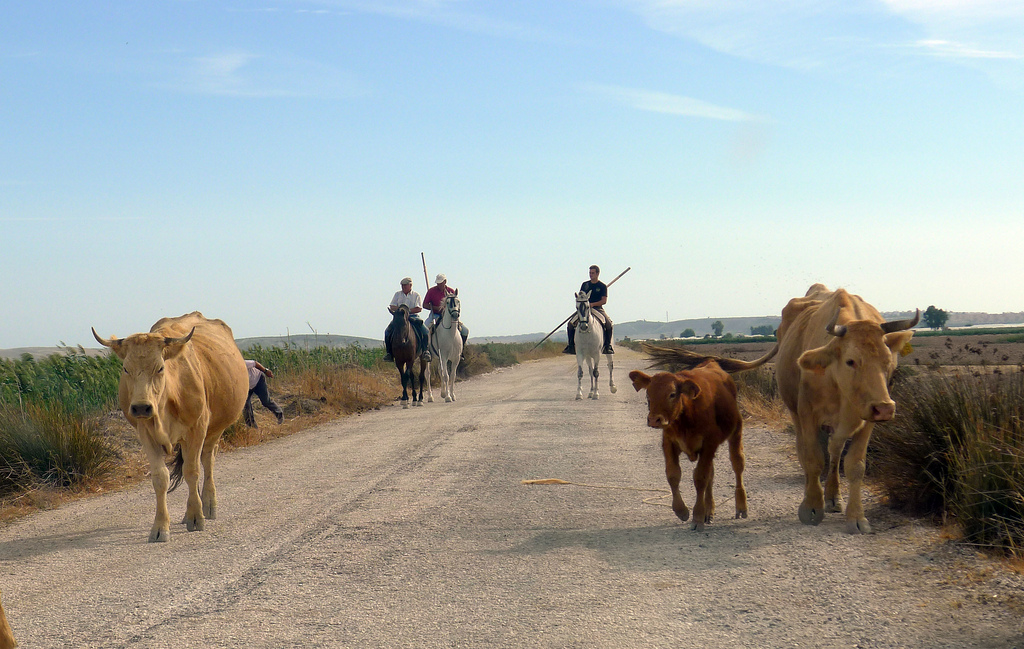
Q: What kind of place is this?
A: It is a road.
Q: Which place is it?
A: It is a road.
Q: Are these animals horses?
A: No, there are both horses and cows.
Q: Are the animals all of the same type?
A: No, there are both horses and cows.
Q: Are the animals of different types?
A: Yes, they are horses and cows.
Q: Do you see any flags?
A: No, there are no flags.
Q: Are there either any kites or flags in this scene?
A: No, there are no flags or kites.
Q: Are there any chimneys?
A: No, there are no chimneys.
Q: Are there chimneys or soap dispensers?
A: No, there are no chimneys or soap dispensers.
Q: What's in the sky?
A: The clouds are in the sky.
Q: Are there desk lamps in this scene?
A: No, there are no desk lamps.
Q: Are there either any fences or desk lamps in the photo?
A: No, there are no desk lamps or fences.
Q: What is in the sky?
A: The clouds are in the sky.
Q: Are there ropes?
A: No, there are no ropes.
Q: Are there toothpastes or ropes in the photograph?
A: No, there are no ropes or toothpastes.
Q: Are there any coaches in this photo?
A: No, there are no coaches.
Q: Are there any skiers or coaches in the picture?
A: No, there are no coaches or skiers.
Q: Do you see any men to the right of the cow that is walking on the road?
A: Yes, there is a man to the right of the cow.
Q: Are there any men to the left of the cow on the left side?
A: No, the man is to the right of the cow.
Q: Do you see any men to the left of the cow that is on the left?
A: No, the man is to the right of the cow.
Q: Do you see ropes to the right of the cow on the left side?
A: No, there is a man to the right of the cow.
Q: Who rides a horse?
A: The man rides a horse.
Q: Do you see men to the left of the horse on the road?
A: Yes, there is a man to the left of the horse.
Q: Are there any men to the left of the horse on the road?
A: Yes, there is a man to the left of the horse.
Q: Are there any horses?
A: Yes, there is a horse.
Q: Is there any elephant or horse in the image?
A: Yes, there is a horse.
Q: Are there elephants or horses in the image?
A: Yes, there is a horse.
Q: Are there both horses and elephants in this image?
A: No, there is a horse but no elephants.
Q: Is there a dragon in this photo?
A: No, there are no dragons.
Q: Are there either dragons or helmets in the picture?
A: No, there are no dragons or helmets.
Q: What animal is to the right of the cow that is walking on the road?
A: The animal is a horse.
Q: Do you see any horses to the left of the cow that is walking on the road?
A: No, the horse is to the right of the cow.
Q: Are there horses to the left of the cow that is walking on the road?
A: No, the horse is to the right of the cow.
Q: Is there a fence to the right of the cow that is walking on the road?
A: No, there is a horse to the right of the cow.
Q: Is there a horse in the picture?
A: Yes, there is a horse.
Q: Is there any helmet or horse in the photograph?
A: Yes, there is a horse.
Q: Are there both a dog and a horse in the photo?
A: No, there is a horse but no dogs.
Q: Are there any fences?
A: No, there are no fences.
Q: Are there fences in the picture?
A: No, there are no fences.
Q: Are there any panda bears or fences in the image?
A: No, there are no fences or panda bears.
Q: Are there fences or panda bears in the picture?
A: No, there are no fences or panda bears.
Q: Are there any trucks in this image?
A: No, there are no trucks.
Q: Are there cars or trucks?
A: No, there are no trucks or cars.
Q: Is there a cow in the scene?
A: Yes, there is a cow.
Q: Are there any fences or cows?
A: Yes, there is a cow.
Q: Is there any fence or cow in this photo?
A: Yes, there is a cow.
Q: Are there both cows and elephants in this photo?
A: No, there is a cow but no elephants.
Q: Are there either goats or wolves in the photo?
A: No, there are no goats or wolves.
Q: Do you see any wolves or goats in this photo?
A: No, there are no goats or wolves.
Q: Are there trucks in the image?
A: No, there are no trucks.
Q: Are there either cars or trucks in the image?
A: No, there are no trucks or cars.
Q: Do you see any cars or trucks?
A: No, there are no trucks or cars.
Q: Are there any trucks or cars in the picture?
A: No, there are no trucks or cars.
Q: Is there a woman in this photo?
A: No, there are no women.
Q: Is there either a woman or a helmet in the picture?
A: No, there are no women or helmets.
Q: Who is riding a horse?
A: The man is riding a horse.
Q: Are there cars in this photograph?
A: No, there are no cars.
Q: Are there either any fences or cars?
A: No, there are no cars or fences.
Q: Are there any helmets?
A: No, there are no helmets.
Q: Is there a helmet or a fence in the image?
A: No, there are no helmets or fences.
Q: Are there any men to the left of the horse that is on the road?
A: Yes, there is a man to the left of the horse.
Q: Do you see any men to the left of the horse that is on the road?
A: Yes, there is a man to the left of the horse.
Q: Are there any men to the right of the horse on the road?
A: No, the man is to the left of the horse.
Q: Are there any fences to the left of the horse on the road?
A: No, there is a man to the left of the horse.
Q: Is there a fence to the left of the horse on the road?
A: No, there is a man to the left of the horse.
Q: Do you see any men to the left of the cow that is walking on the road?
A: No, the man is to the right of the cow.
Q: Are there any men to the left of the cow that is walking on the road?
A: No, the man is to the right of the cow.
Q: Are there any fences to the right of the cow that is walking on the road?
A: No, there is a man to the right of the cow.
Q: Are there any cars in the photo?
A: No, there are no cars.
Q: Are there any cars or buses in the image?
A: No, there are no cars or buses.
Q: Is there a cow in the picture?
A: Yes, there is a cow.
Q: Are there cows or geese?
A: Yes, there is a cow.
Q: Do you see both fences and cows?
A: No, there is a cow but no fences.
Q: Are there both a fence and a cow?
A: No, there is a cow but no fences.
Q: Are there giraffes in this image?
A: No, there are no giraffes.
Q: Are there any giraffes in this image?
A: No, there are no giraffes.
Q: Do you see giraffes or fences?
A: No, there are no giraffes or fences.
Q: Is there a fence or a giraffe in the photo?
A: No, there are no giraffes or fences.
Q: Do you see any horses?
A: Yes, there is a horse.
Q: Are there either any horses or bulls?
A: Yes, there is a horse.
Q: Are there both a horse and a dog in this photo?
A: No, there is a horse but no dogs.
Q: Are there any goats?
A: No, there are no goats.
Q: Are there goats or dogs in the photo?
A: No, there are no goats or dogs.